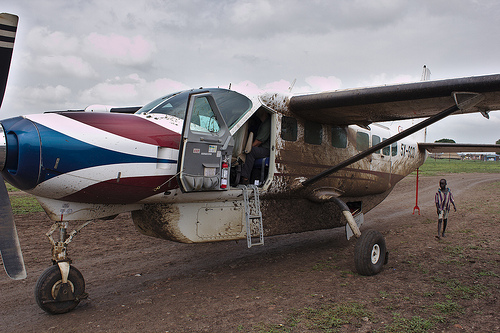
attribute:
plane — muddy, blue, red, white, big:
[4, 71, 500, 311]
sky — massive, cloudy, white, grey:
[1, 4, 499, 135]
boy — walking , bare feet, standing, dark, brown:
[427, 172, 465, 244]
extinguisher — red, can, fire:
[214, 153, 244, 196]